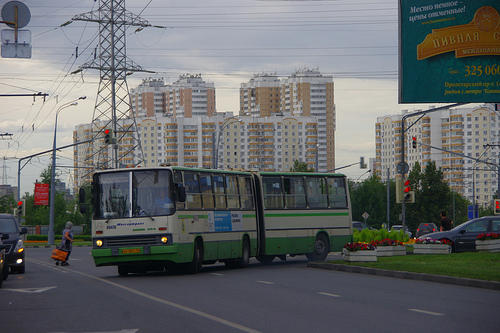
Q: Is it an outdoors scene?
A: Yes, it is outdoors.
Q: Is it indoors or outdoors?
A: It is outdoors.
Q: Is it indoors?
A: No, it is outdoors.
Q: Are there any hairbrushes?
A: No, there are no hairbrushes.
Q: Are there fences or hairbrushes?
A: No, there are no hairbrushes or fences.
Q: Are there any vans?
A: No, there are no vans.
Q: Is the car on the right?
A: Yes, the car is on the right of the image.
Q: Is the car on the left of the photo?
A: No, the car is on the right of the image.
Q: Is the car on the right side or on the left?
A: The car is on the right of the image.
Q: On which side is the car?
A: The car is on the right of the image.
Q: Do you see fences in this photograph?
A: No, there are no fences.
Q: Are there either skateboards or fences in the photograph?
A: No, there are no fences or skateboards.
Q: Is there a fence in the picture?
A: No, there are no fences.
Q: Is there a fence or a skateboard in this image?
A: No, there are no fences or skateboards.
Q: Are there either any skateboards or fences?
A: No, there are no fences or skateboards.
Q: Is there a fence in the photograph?
A: No, there are no fences.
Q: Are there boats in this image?
A: No, there are no boats.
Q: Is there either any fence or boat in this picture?
A: No, there are no boats or fences.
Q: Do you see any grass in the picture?
A: Yes, there is grass.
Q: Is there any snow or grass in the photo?
A: Yes, there is grass.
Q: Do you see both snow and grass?
A: No, there is grass but no snow.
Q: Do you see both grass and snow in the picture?
A: No, there is grass but no snow.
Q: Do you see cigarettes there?
A: No, there are no cigarettes.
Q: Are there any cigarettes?
A: No, there are no cigarettes.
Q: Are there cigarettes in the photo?
A: No, there are no cigarettes.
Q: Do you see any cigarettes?
A: No, there are no cigarettes.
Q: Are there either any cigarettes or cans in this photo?
A: No, there are no cigarettes or cans.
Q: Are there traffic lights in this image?
A: Yes, there is a traffic light.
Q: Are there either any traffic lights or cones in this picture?
A: Yes, there is a traffic light.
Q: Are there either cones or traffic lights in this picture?
A: Yes, there is a traffic light.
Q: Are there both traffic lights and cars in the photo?
A: Yes, there are both a traffic light and cars.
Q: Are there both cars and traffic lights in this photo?
A: Yes, there are both a traffic light and cars.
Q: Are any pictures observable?
A: No, there are no pictures.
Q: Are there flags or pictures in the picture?
A: No, there are no pictures or flags.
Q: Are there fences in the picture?
A: No, there are no fences.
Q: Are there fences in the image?
A: No, there are no fences.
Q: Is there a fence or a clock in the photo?
A: No, there are no fences or clocks.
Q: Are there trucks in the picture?
A: No, there are no trucks.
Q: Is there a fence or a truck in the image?
A: No, there are no trucks or fences.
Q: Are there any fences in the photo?
A: No, there are no fences.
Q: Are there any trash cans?
A: No, there are no trash cans.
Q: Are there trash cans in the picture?
A: No, there are no trash cans.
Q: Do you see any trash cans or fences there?
A: No, there are no trash cans or fences.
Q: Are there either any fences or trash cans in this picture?
A: No, there are no trash cans or fences.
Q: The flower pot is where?
A: The flower pot is on the grass.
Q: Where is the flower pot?
A: The flower pot is on the grass.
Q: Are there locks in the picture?
A: No, there are no locks.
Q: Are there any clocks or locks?
A: No, there are no locks or clocks.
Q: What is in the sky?
A: The clouds are in the sky.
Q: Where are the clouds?
A: The clouds are in the sky.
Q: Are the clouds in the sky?
A: Yes, the clouds are in the sky.